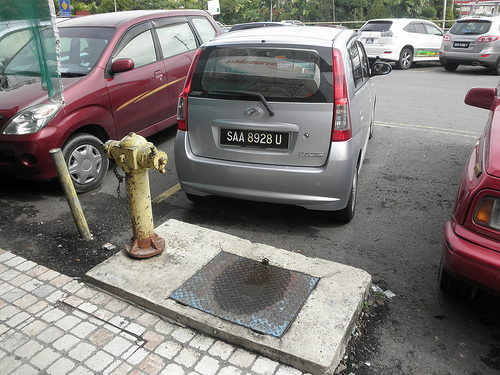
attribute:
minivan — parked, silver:
[170, 23, 378, 223]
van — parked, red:
[0, 10, 219, 191]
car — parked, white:
[356, 18, 445, 72]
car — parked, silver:
[441, 17, 499, 69]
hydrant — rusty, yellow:
[99, 131, 170, 259]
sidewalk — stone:
[2, 247, 314, 375]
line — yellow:
[152, 183, 181, 203]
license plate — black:
[219, 126, 289, 148]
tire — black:
[396, 48, 414, 69]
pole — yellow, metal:
[47, 146, 95, 240]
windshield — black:
[193, 46, 333, 105]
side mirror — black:
[369, 61, 391, 77]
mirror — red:
[113, 59, 135, 74]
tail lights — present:
[331, 47, 353, 141]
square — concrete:
[82, 217, 376, 375]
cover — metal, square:
[168, 254, 321, 337]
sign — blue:
[58, 2, 71, 16]